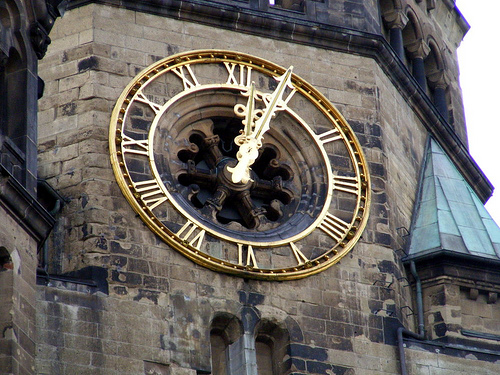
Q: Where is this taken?
A: Front of clock tower.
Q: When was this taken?
A: Daytime.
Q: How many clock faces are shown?
A: 1.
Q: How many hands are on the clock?
A: 2.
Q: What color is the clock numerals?
A: Gold.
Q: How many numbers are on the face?
A: 12.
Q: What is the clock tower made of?
A: Stone.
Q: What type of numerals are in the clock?
A: Roman.